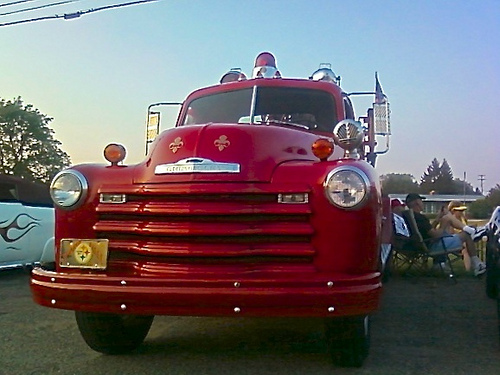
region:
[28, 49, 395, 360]
Parked red truck on pavement.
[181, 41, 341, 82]
Siren lights on a red truck.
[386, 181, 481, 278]
Men and a woman.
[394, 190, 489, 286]
Woman and men sitting in chairs.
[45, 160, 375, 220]
Front headlights on a red truck.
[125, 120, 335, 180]
The hood on a red truck.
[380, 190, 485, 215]
House on the other side of the street.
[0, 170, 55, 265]
White car with black top.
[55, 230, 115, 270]
Yellow tag on a red fire truck.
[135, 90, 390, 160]
Side mirrors on a red truck.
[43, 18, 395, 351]
An antique red truck.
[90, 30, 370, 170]
The truck has a siren and lights on it.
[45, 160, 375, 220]
The truck's headlights.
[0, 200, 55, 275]
A flame design on the car door.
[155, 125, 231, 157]
The fleurs-de-lis.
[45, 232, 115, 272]
A Pittsburgh Steelers decorative license plate.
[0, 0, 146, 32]
Power lines.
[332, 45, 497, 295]
A group of people sitting next to the truck.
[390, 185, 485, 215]
A building in the background.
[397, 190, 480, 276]
The man is wearing shorts.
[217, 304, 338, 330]
silver studs on front of red truck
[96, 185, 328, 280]
groves in front of truck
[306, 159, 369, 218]
large circle light on truck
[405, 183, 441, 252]
man sitting on plastic chair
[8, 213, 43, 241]
gold design on white fence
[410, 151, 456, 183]
top of tall green trees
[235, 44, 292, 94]
large red siren on top of truck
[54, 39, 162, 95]
clear blue and white skies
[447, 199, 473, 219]
sun visor on woman's head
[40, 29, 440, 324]
large red truck on ground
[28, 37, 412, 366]
red fire truck parked on grass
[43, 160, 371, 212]
two round headlights trimmed in chrome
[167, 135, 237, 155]
two gold fleur de lis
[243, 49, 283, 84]
red fire engine light with chrome base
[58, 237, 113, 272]
gold license plate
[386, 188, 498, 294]
people sitting outside in folding chairs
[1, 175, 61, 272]
side of white vehicle with red flame design on side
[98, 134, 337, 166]
two round orange lights mounted on truck's hood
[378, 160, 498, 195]
trees and electrical poles in background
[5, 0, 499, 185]
bright blue clear sky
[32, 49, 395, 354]
an antique fire truck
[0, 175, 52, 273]
older white car with flames painted on it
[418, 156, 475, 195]
evergreen trees in the background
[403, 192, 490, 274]
man and woman sitting in lawn chairs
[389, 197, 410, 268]
man sits in a lawn chair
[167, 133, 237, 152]
emblems painted on the hood of the firetruck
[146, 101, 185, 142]
rearview mirror on the firetruck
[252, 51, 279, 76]
red light on top of the firetruck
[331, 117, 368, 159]
siren on the firetruck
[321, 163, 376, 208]
one of the firetruck's headlights